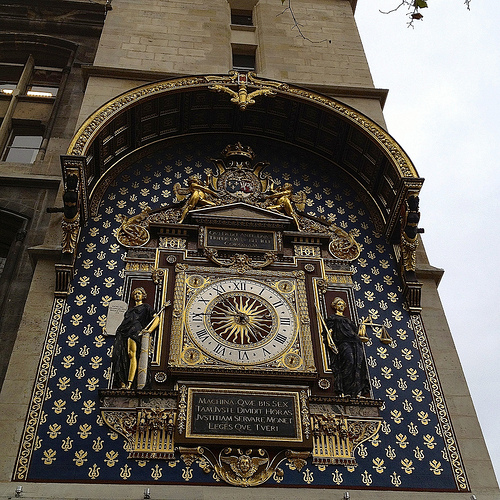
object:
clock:
[168, 263, 319, 378]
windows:
[228, 0, 265, 73]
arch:
[54, 67, 426, 314]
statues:
[111, 287, 372, 399]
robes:
[112, 302, 372, 395]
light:
[0, 89, 53, 98]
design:
[9, 59, 473, 492]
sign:
[176, 384, 312, 448]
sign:
[201, 222, 278, 252]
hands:
[202, 299, 260, 341]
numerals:
[193, 282, 290, 359]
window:
[0, 33, 77, 163]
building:
[0, 1, 499, 500]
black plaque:
[207, 228, 274, 250]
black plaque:
[191, 391, 301, 437]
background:
[383, 352, 430, 491]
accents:
[11, 125, 471, 491]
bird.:
[204, 70, 285, 111]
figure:
[221, 448, 268, 481]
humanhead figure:
[235, 252, 249, 274]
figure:
[314, 296, 369, 398]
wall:
[88, 0, 374, 80]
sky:
[354, 0, 500, 497]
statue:
[264, 182, 303, 233]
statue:
[174, 167, 217, 224]